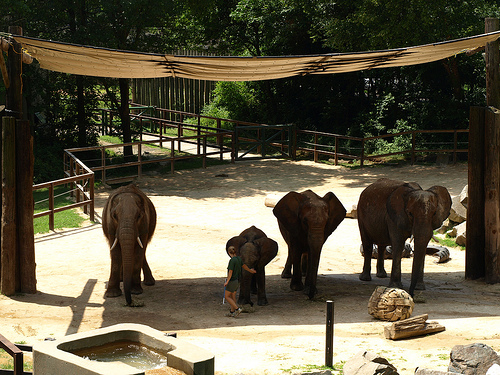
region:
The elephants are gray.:
[79, 184, 455, 309]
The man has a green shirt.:
[218, 239, 257, 311]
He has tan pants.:
[208, 271, 243, 301]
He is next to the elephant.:
[207, 239, 271, 319]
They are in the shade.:
[50, 169, 486, 335]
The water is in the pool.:
[61, 325, 160, 373]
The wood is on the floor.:
[365, 279, 432, 350]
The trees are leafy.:
[205, 6, 492, 168]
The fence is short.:
[125, 100, 470, 180]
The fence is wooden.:
[58, 132, 466, 174]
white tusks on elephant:
[99, 225, 169, 272]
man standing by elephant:
[222, 245, 252, 330]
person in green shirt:
[221, 245, 248, 290]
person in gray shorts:
[216, 256, 246, 308]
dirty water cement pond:
[57, 334, 173, 374]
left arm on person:
[220, 262, 235, 284]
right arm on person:
[239, 263, 265, 279]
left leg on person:
[221, 289, 253, 313]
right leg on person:
[224, 300, 238, 311]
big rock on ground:
[345, 288, 421, 325]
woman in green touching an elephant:
[223, 247, 254, 317]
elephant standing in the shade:
[103, 185, 154, 306]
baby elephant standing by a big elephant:
[226, 225, 278, 307]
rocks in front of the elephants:
[288, 343, 498, 374]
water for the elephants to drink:
[68, 337, 170, 369]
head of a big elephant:
[388, 183, 452, 299]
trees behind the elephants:
[30, 25, 483, 176]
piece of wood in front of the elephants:
[383, 313, 443, 340]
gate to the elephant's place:
[236, 125, 298, 159]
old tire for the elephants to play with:
[360, 242, 412, 257]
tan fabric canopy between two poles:
[6, 11, 491, 91]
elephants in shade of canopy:
[80, 175, 471, 310]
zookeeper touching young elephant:
[220, 220, 280, 310]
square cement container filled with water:
[35, 315, 211, 370]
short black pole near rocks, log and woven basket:
[320, 280, 495, 370]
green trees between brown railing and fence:
[30, 5, 480, 230]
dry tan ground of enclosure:
[5, 150, 485, 370]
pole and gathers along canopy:
[147, 45, 409, 80]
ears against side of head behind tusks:
[95, 185, 160, 310]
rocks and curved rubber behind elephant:
[352, 157, 464, 262]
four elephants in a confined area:
[100, 178, 450, 310]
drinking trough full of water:
[33, 322, 214, 373]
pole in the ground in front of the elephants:
[323, 296, 340, 366]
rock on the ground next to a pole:
[339, 349, 399, 373]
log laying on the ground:
[383, 309, 450, 341]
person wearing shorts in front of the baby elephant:
[222, 246, 259, 318]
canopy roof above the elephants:
[0, 27, 498, 82]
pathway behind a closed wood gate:
[58, 120, 263, 157]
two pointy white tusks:
[109, 236, 146, 250]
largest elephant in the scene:
[358, 176, 453, 303]